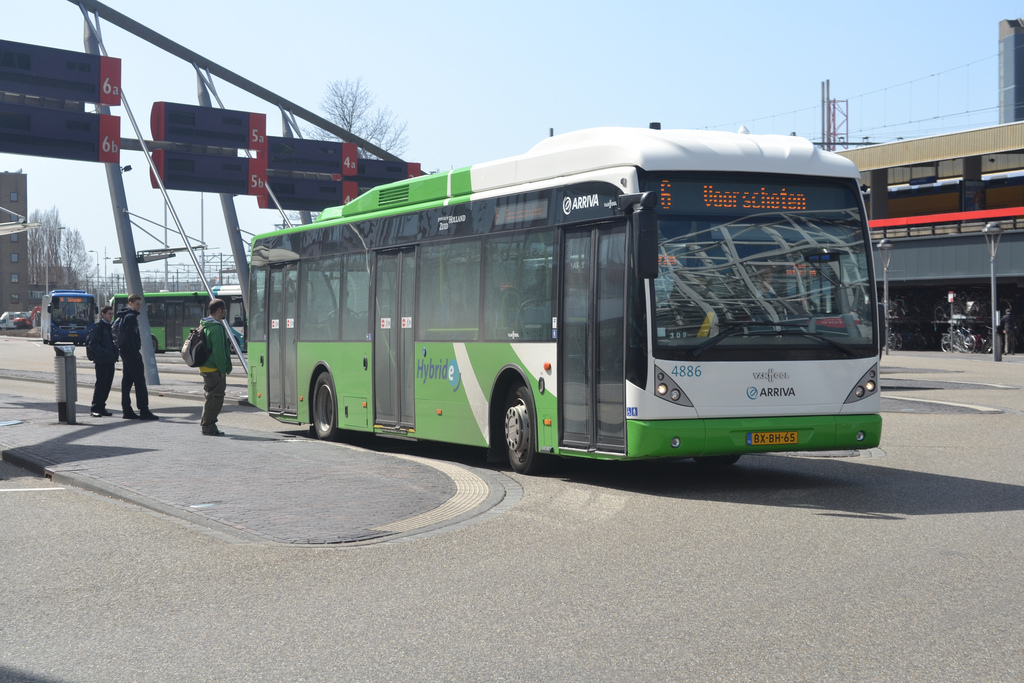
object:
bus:
[243, 123, 887, 474]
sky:
[715, 11, 803, 75]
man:
[195, 298, 231, 436]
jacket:
[192, 317, 233, 377]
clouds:
[365, 17, 608, 133]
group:
[85, 294, 232, 436]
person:
[113, 293, 160, 420]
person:
[83, 305, 118, 417]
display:
[647, 175, 861, 219]